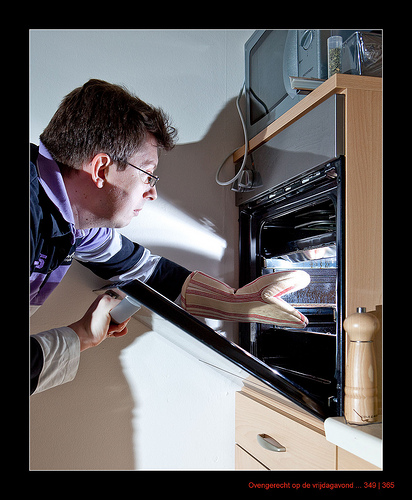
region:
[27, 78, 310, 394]
a man reaching into an oven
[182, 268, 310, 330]
an oven mitt on the man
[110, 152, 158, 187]
glasses on the man's face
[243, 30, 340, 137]
microwave above the oven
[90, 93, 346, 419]
a black oven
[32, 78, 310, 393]
man is looking in an oven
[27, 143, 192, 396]
mans shirt is blue and white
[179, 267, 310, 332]
oven mitt is red and white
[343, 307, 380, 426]
pepper shaker is wooden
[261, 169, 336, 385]
oven is dirty and silver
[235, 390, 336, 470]
drawer is cream colored with a handle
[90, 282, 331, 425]
oven door is open and silver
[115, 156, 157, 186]
glasses are on the mans face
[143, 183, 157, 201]
nose on the man making dinner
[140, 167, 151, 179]
eye on the man making dinner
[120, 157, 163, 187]
glasses on the man making dinner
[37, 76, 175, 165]
hair on the man making dinner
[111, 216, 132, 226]
chin on the man making dinner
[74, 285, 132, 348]
hand on the man making dinner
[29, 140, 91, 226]
neck on the man making dinner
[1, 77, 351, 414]
Man reaching into oven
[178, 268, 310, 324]
Oven mitt on man's hand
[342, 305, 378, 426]
Pepper shaker on the counter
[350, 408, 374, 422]
Crack in the pepper shaker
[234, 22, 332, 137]
Microwave oven on top of the shelf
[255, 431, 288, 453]
Silver handle on cabinet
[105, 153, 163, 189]
Glasses on man's eyes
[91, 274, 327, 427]
Open oven door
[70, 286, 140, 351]
Man's hand holding oven door handle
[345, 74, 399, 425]
Wooden panel along side of microwave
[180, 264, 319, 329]
A striped oven mitt reaching inside an oven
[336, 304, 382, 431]
A tall thick wooden pepper dispenser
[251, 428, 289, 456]
Silver thin drawer handle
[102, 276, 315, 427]
The edge of an oven door being held open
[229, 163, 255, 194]
Two round oven dials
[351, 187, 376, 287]
Pale blond woodgrain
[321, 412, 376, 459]
The white rounded edge of a kitchen counter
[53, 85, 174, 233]
The profile of a middle-aged man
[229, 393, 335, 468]
A pale wood kitchen door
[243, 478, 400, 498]
Orange text on a black background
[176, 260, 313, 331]
oven mitt on the left hand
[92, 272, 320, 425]
door of the oven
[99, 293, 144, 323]
grey handle of the oven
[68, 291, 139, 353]
right hand on the handle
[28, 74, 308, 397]
man reaching into an oven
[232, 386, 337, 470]
light wood drawer with silver handle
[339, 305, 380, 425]
light brown wood pepper grinder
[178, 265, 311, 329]
beige and red striped oven mitt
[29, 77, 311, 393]
man wearing glasses and oven mitt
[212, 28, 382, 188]
silver microwave with gray power cord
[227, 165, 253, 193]
two silver oven knobs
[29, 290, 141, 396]
sleeved arm opening oven door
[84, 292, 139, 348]
hand grasping oven door handle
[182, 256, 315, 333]
light yellow and red oven mitt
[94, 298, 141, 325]
handle on the oven door